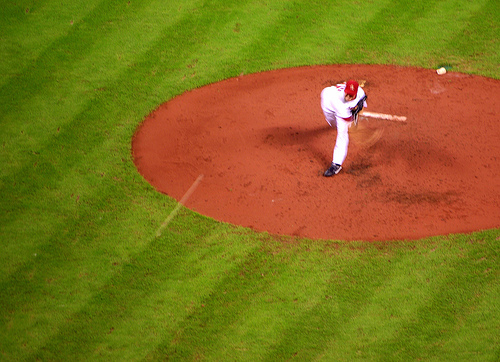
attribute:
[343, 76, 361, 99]
hat — red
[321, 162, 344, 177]
shoe — black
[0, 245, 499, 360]
grass — green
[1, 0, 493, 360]
ground — green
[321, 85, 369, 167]
clothing — white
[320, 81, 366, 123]
shirt — white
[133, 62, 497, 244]
mound — round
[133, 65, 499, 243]
dirt — brown